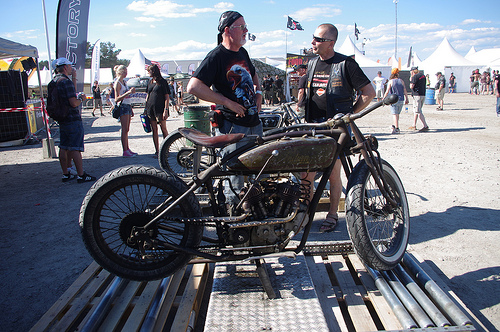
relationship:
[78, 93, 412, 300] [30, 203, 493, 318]
motorbike on structure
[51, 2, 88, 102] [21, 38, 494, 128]
banner near crowd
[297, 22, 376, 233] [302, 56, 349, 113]
man wearing vest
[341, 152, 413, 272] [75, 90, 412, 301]
front tire on motorcycle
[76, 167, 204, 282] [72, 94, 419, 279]
tire on motorcycle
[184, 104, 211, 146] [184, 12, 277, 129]
drum behind man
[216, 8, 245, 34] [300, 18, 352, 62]
bandana on head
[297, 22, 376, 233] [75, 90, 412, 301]
man standing behind motorcycle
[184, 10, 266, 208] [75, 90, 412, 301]
man standing behind motorcycle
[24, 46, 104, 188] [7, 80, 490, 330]
man standing in area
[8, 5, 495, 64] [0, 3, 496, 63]
clouds are in sky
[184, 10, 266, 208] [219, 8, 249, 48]
man has head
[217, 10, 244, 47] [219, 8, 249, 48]
bandana tied at back of head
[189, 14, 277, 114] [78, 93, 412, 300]
man standing near motorbike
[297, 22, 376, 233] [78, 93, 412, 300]
man standing near motorbike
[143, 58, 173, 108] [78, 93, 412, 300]
man standing near motorbike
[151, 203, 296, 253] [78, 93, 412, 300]
chain on motorbike